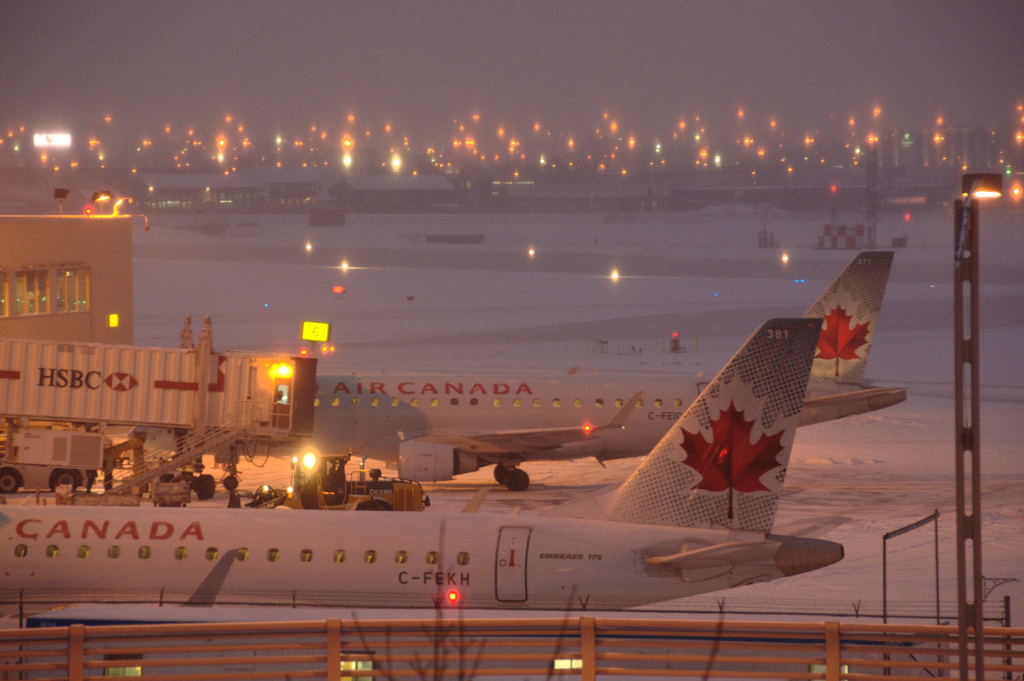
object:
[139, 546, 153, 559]
windows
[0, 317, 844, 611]
airplane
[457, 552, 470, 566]
window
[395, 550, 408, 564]
window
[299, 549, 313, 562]
window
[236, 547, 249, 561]
window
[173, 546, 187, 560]
window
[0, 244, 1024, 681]
runway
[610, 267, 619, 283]
light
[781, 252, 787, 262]
light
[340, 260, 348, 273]
light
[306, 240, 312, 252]
light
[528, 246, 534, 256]
light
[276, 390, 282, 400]
passenger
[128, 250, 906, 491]
airplane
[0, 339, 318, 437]
loading apparatus